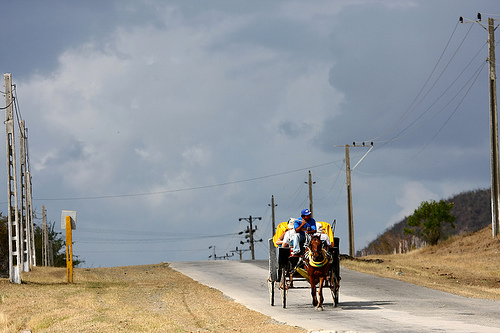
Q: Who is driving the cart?
A: A man.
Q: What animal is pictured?
A: Horse.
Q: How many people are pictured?
A: One.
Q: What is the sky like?
A: Cloudy.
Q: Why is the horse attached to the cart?
A: Pulling it.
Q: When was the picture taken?
A: Daytime.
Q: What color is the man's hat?
A: Blue.